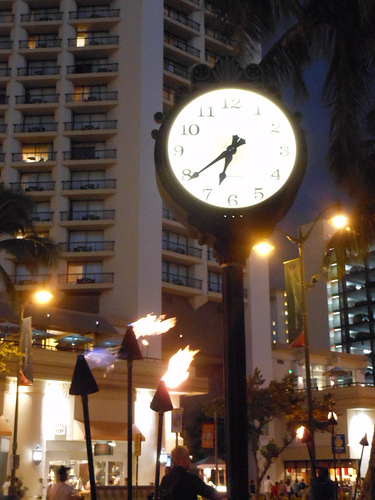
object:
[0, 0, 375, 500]
night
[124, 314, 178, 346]
gust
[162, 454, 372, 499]
crowd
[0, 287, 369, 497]
shopping center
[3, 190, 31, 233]
branches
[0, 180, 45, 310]
tree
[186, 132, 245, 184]
hands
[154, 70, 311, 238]
clock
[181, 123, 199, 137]
number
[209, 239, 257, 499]
pole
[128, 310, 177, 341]
flame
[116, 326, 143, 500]
torch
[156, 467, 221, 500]
shirt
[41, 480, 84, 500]
shirt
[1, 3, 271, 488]
building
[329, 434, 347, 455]
sign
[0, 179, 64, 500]
tree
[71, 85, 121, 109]
balcony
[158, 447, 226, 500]
person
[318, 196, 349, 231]
street light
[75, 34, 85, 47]
light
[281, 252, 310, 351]
flag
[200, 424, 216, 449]
banner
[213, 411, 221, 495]
pole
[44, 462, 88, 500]
woman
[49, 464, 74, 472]
hat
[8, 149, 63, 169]
balcony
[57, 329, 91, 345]
umbrella